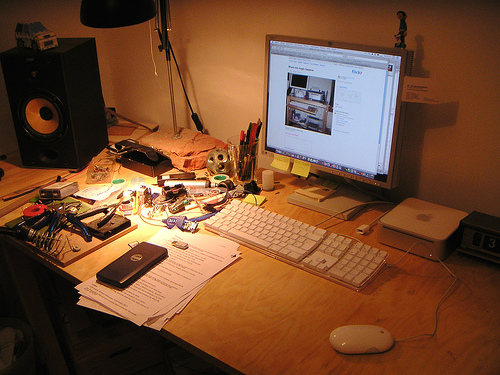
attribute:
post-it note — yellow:
[288, 154, 313, 186]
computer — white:
[377, 194, 466, 267]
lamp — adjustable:
[77, 1, 196, 141]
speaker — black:
[0, 36, 108, 167]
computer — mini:
[206, 34, 473, 295]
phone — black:
[97, 241, 168, 288]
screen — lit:
[258, 32, 412, 194]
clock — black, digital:
[454, 207, 499, 268]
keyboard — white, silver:
[202, 190, 424, 292]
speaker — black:
[9, 35, 109, 174]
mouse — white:
[302, 301, 412, 360]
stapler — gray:
[97, 127, 172, 173]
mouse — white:
[326, 316, 397, 356]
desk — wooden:
[4, 115, 498, 370]